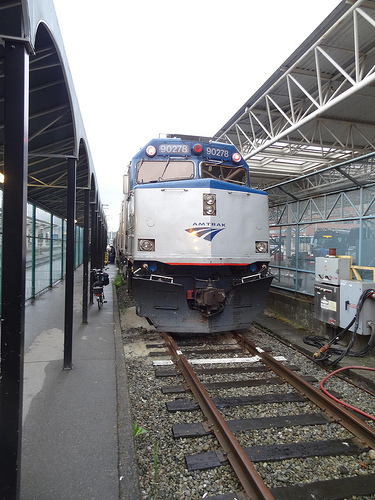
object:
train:
[112, 133, 274, 336]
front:
[129, 138, 276, 334]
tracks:
[165, 325, 374, 498]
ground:
[20, 264, 374, 499]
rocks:
[138, 399, 171, 497]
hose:
[320, 364, 375, 421]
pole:
[65, 158, 77, 370]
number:
[159, 145, 228, 158]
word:
[193, 221, 226, 227]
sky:
[74, 0, 243, 63]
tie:
[183, 434, 374, 472]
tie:
[171, 410, 336, 439]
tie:
[201, 474, 374, 499]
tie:
[166, 388, 310, 412]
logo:
[184, 222, 226, 243]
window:
[136, 159, 196, 184]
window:
[198, 160, 249, 187]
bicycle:
[90, 267, 109, 309]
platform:
[21, 262, 138, 499]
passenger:
[108, 246, 115, 264]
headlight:
[203, 194, 216, 215]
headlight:
[138, 239, 155, 251]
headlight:
[255, 241, 268, 253]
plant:
[132, 420, 148, 437]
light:
[194, 145, 202, 153]